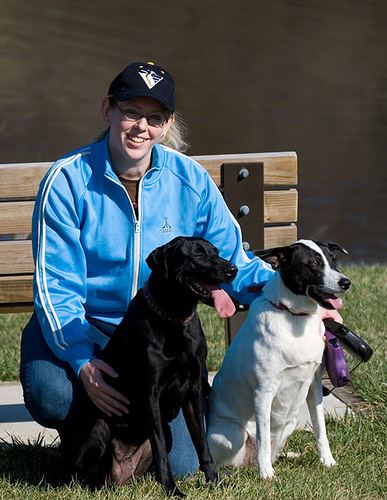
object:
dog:
[61, 234, 237, 500]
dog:
[205, 238, 351, 481]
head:
[252, 239, 351, 312]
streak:
[295, 239, 330, 269]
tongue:
[207, 285, 236, 319]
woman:
[20, 62, 278, 481]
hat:
[108, 61, 176, 116]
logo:
[137, 69, 164, 90]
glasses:
[117, 105, 164, 129]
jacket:
[30, 130, 277, 381]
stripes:
[42, 151, 92, 347]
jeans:
[18, 309, 207, 479]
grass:
[0, 267, 387, 500]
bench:
[0, 149, 298, 313]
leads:
[322, 318, 373, 363]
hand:
[319, 302, 344, 341]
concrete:
[4, 383, 17, 406]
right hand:
[77, 360, 130, 419]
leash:
[324, 330, 349, 388]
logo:
[161, 217, 174, 234]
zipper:
[104, 165, 157, 300]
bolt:
[239, 169, 250, 180]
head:
[102, 60, 175, 159]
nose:
[134, 115, 148, 133]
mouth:
[125, 134, 151, 146]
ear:
[101, 96, 111, 124]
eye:
[125, 109, 139, 116]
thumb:
[95, 360, 119, 380]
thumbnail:
[113, 371, 118, 377]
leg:
[142, 392, 189, 500]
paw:
[166, 485, 188, 500]